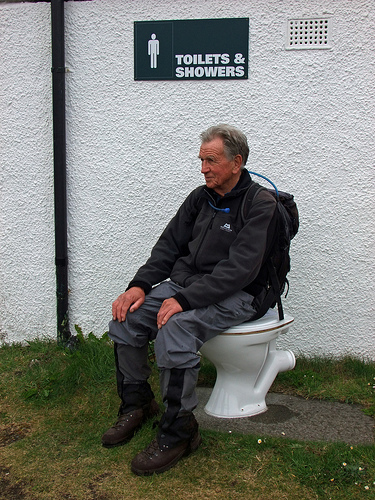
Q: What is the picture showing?
A: It is showing a lawn.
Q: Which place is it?
A: It is a lawn.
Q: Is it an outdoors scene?
A: Yes, it is outdoors.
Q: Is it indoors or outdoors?
A: It is outdoors.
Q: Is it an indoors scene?
A: No, it is outdoors.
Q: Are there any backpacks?
A: Yes, there is a backpack.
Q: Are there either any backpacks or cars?
A: Yes, there is a backpack.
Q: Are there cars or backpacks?
A: Yes, there is a backpack.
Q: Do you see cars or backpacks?
A: Yes, there is a backpack.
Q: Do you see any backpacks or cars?
A: Yes, there is a backpack.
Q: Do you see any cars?
A: No, there are no cars.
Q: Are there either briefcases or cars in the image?
A: No, there are no cars or briefcases.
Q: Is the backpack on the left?
A: No, the backpack is on the right of the image.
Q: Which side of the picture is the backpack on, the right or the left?
A: The backpack is on the right of the image.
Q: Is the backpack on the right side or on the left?
A: The backpack is on the right of the image.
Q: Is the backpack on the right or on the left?
A: The backpack is on the right of the image.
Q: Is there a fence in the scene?
A: No, there are no fences.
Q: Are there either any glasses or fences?
A: No, there are no fences or glasses.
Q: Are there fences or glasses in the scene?
A: No, there are no fences or glasses.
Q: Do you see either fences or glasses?
A: No, there are no fences or glasses.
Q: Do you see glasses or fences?
A: No, there are no fences or glasses.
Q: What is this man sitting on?
A: The man is sitting on the toilet.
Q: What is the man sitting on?
A: The man is sitting on the toilet.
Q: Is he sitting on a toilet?
A: Yes, the man is sitting on a toilet.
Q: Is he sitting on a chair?
A: No, the man is sitting on a toilet.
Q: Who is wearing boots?
A: The man is wearing boots.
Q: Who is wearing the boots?
A: The man is wearing boots.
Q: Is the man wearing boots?
A: Yes, the man is wearing boots.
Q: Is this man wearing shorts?
A: No, the man is wearing boots.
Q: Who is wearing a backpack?
A: The man is wearing a backpack.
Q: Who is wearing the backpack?
A: The man is wearing a backpack.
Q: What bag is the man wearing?
A: The man is wearing a backpack.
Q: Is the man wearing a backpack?
A: Yes, the man is wearing a backpack.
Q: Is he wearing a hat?
A: No, the man is wearing a backpack.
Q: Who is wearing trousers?
A: The man is wearing trousers.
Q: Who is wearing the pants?
A: The man is wearing trousers.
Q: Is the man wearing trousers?
A: Yes, the man is wearing trousers.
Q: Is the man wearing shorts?
A: No, the man is wearing trousers.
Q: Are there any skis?
A: No, there are no skis.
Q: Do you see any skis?
A: No, there are no skis.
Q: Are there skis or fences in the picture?
A: No, there are no skis or fences.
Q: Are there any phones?
A: No, there are no phones.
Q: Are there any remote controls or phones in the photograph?
A: No, there are no phones or remote controls.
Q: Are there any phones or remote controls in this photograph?
A: No, there are no phones or remote controls.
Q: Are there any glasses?
A: No, there are no glasses.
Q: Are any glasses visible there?
A: No, there are no glasses.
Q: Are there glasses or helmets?
A: No, there are no glasses or helmets.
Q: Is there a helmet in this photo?
A: No, there are no helmets.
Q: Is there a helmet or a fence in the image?
A: No, there are no helmets or fences.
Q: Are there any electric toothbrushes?
A: No, there are no electric toothbrushes.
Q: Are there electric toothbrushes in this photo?
A: No, there are no electric toothbrushes.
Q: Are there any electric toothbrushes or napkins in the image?
A: No, there are no electric toothbrushes or napkins.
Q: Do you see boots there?
A: Yes, there are boots.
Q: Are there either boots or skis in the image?
A: Yes, there are boots.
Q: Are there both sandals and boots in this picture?
A: No, there are boots but no sandals.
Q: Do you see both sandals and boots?
A: No, there are boots but no sandals.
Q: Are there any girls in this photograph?
A: No, there are no girls.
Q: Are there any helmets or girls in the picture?
A: No, there are no girls or helmets.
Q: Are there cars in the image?
A: No, there are no cars.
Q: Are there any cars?
A: No, there are no cars.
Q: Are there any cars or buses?
A: No, there are no cars or buses.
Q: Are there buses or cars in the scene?
A: No, there are no cars or buses.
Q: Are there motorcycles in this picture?
A: No, there are no motorcycles.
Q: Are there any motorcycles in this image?
A: No, there are no motorcycles.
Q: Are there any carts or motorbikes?
A: No, there are no motorbikes or carts.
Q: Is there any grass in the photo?
A: Yes, there is grass.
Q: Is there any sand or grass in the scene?
A: Yes, there is grass.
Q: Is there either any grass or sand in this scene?
A: Yes, there is grass.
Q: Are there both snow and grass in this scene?
A: No, there is grass but no snow.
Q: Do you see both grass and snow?
A: No, there is grass but no snow.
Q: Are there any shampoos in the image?
A: No, there are no shampoos.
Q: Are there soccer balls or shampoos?
A: No, there are no shampoos or soccer balls.